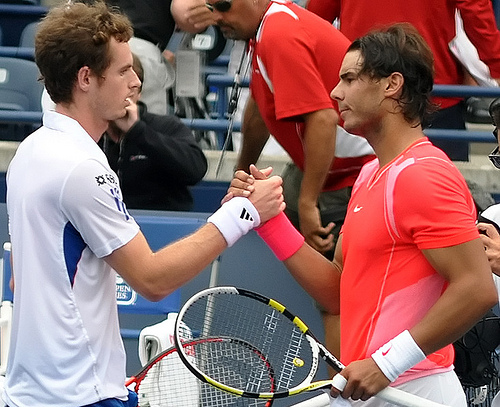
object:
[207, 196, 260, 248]
wrist band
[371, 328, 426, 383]
wrist band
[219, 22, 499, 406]
man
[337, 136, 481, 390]
shirt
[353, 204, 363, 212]
nike logo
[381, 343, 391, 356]
nike logo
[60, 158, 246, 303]
arm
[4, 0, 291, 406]
man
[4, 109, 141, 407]
shirt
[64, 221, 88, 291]
patch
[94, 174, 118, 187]
lettering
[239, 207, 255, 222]
logo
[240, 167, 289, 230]
hands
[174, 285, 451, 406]
tennis racket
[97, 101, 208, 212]
jacket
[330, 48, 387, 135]
game face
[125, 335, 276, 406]
tennis racket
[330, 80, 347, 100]
nose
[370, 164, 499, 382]
arm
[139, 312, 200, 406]
towel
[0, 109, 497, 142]
pole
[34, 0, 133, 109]
hair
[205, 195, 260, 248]
wrist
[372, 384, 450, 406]
grip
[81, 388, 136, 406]
shorts